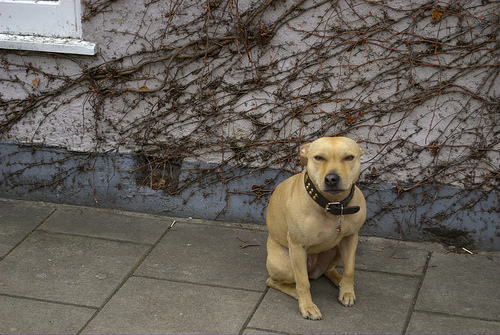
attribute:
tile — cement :
[132, 215, 284, 295]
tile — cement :
[7, 197, 497, 328]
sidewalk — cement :
[388, 254, 487, 321]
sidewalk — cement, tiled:
[21, 200, 498, 325]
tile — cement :
[29, 204, 151, 266]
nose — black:
[323, 172, 342, 187]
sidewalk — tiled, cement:
[1, 194, 499, 328]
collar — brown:
[302, 163, 362, 214]